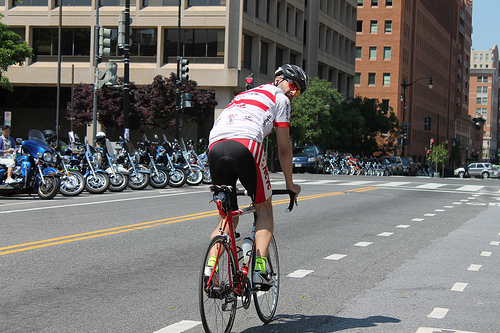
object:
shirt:
[208, 83, 292, 148]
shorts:
[208, 139, 272, 211]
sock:
[254, 256, 268, 273]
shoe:
[252, 269, 276, 285]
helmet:
[274, 63, 309, 96]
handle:
[236, 188, 298, 213]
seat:
[209, 185, 245, 196]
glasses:
[281, 77, 302, 97]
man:
[203, 64, 308, 296]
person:
[0, 124, 19, 183]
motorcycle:
[0, 129, 60, 200]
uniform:
[208, 83, 291, 211]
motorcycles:
[50, 140, 87, 196]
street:
[3, 198, 497, 331]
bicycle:
[197, 185, 297, 332]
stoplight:
[430, 138, 434, 142]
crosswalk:
[309, 179, 498, 197]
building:
[351, 1, 474, 98]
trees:
[67, 77, 136, 142]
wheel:
[198, 235, 238, 332]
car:
[454, 162, 497, 178]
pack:
[212, 191, 228, 216]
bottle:
[241, 236, 254, 266]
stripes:
[346, 186, 379, 192]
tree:
[427, 143, 450, 179]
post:
[428, 151, 433, 176]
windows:
[369, 46, 377, 60]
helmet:
[95, 132, 106, 143]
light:
[245, 72, 254, 91]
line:
[396, 224, 411, 229]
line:
[353, 241, 373, 246]